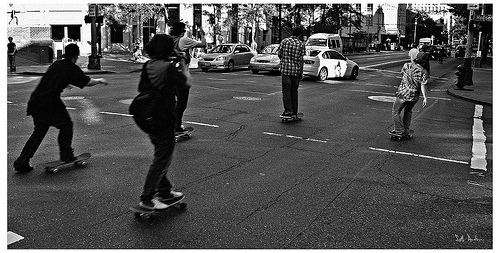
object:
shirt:
[276, 37, 305, 76]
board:
[128, 191, 187, 225]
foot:
[132, 188, 185, 212]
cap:
[63, 43, 81, 59]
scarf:
[407, 48, 424, 62]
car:
[305, 46, 360, 82]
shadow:
[308, 53, 320, 77]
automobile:
[197, 44, 255, 72]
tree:
[113, 7, 141, 57]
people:
[10, 30, 469, 219]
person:
[276, 29, 305, 123]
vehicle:
[248, 43, 280, 74]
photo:
[0, 0, 500, 253]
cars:
[182, 23, 375, 81]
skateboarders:
[273, 113, 304, 120]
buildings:
[0, 0, 500, 57]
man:
[389, 49, 436, 141]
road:
[0, 70, 500, 249]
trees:
[205, 7, 366, 36]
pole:
[454, 8, 474, 89]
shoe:
[59, 144, 80, 163]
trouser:
[390, 95, 419, 133]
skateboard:
[42, 153, 91, 174]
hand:
[89, 78, 109, 87]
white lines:
[470, 103, 488, 171]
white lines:
[368, 147, 470, 171]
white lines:
[259, 129, 329, 146]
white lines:
[179, 120, 219, 128]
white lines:
[98, 112, 134, 117]